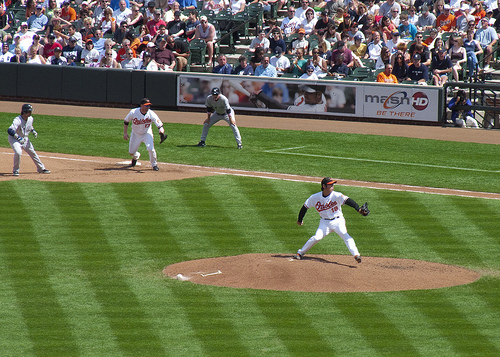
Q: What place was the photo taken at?
A: It was taken at the field.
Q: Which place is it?
A: It is a field.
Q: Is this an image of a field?
A: Yes, it is showing a field.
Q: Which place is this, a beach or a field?
A: It is a field.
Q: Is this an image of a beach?
A: No, the picture is showing a field.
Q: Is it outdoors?
A: Yes, it is outdoors.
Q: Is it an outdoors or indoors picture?
A: It is outdoors.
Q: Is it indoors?
A: No, it is outdoors.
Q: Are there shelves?
A: No, there are no shelves.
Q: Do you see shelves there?
A: No, there are no shelves.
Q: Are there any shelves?
A: No, there are no shelves.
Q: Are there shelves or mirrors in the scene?
A: No, there are no shelves or mirrors.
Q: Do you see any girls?
A: No, there are no girls.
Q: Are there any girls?
A: No, there are no girls.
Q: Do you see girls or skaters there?
A: No, there are no girls or skaters.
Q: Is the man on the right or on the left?
A: The man is on the right of the image.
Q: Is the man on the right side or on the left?
A: The man is on the right of the image.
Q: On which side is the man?
A: The man is on the right of the image.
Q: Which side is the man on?
A: The man is on the right of the image.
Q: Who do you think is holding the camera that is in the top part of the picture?
A: The man is holding the camera.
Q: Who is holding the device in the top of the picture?
A: The man is holding the camera.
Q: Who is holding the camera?
A: The man is holding the camera.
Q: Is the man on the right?
A: Yes, the man is on the right of the image.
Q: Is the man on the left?
A: No, the man is on the right of the image.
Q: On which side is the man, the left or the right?
A: The man is on the right of the image.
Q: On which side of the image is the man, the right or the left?
A: The man is on the right of the image.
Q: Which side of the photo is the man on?
A: The man is on the right of the image.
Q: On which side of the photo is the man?
A: The man is on the right of the image.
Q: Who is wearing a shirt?
A: The man is wearing a shirt.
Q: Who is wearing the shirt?
A: The man is wearing a shirt.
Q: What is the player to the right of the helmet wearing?
A: The player is wearing a glove.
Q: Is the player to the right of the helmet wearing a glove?
A: Yes, the player is wearing a glove.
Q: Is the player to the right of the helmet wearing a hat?
A: No, the player is wearing a glove.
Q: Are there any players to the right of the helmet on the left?
A: Yes, there is a player to the right of the helmet.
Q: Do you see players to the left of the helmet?
A: No, the player is to the right of the helmet.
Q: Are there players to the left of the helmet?
A: No, the player is to the right of the helmet.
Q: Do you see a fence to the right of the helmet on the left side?
A: No, there is a player to the right of the helmet.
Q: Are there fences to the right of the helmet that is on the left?
A: No, there is a player to the right of the helmet.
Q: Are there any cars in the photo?
A: No, there are no cars.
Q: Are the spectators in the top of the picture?
A: Yes, the spectators are in the top of the image.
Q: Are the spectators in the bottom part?
A: No, the spectators are in the top of the image.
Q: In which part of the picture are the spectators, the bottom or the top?
A: The spectators are in the top of the image.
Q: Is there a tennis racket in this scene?
A: No, there are no rackets.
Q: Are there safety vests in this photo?
A: No, there are no safety vests.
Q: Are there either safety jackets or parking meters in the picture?
A: No, there are no safety jackets or parking meters.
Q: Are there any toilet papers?
A: No, there are no toilet papers.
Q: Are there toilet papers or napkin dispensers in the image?
A: No, there are no toilet papers or napkin dispensers.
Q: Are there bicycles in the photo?
A: No, there are no bicycles.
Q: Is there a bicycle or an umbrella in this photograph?
A: No, there are no bicycles or umbrellas.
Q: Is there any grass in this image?
A: Yes, there is grass.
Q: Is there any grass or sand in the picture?
A: Yes, there is grass.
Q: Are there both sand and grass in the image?
A: No, there is grass but no sand.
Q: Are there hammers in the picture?
A: No, there are no hammers.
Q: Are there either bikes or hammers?
A: No, there are no hammers or bikes.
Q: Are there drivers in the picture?
A: No, there are no drivers.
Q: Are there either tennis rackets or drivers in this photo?
A: No, there are no drivers or tennis rackets.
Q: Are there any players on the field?
A: Yes, there is a player on the field.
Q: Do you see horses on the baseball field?
A: No, there is a player on the field.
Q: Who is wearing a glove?
A: The player is wearing a glove.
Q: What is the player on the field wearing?
A: The player is wearing a glove.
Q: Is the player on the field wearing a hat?
A: No, the player is wearing a glove.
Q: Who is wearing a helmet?
A: The player is wearing a helmet.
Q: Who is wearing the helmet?
A: The player is wearing a helmet.